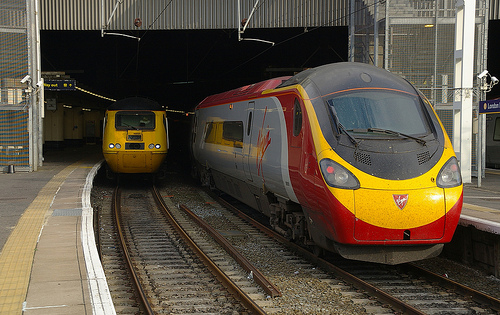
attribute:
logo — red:
[392, 192, 409, 211]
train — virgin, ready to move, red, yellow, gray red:
[189, 58, 467, 270]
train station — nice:
[2, 3, 499, 179]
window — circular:
[246, 111, 255, 137]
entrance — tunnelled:
[32, 22, 363, 176]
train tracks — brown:
[109, 173, 266, 314]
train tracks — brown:
[212, 186, 491, 314]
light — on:
[154, 141, 163, 151]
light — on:
[107, 144, 115, 150]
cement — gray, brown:
[1, 149, 117, 314]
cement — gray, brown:
[430, 157, 499, 220]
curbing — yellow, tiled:
[0, 154, 76, 312]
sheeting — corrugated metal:
[1, 2, 498, 31]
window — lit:
[8, 88, 23, 105]